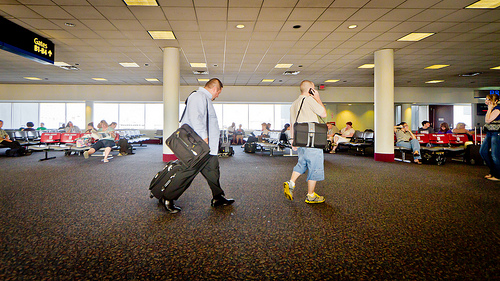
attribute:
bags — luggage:
[165, 125, 205, 164]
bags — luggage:
[150, 154, 187, 198]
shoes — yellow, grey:
[277, 177, 332, 207]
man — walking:
[151, 78, 238, 219]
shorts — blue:
[285, 136, 329, 179]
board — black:
[0, 19, 60, 72]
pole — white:
[372, 47, 394, 154]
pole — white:
[160, 47, 182, 154]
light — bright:
[135, 15, 175, 46]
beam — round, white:
[374, 54, 394, 158]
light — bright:
[239, 22, 320, 104]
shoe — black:
[154, 197, 184, 217]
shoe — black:
[208, 191, 239, 215]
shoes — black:
[154, 189, 240, 219]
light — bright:
[189, 62, 208, 70]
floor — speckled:
[3, 160, 485, 271]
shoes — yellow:
[280, 181, 326, 204]